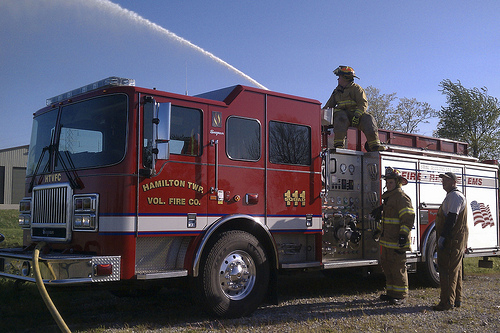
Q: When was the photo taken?
A: Daytime.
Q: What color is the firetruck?
A: Red.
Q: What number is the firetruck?
A: 111.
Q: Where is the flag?
A: Truck.